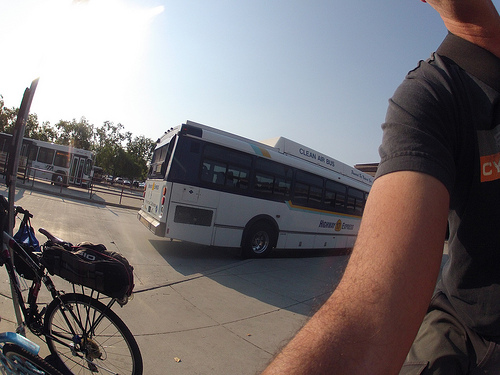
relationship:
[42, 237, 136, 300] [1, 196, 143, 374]
bag on bicycle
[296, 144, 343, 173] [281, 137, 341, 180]
writting on side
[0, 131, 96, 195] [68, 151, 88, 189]
bus has double doors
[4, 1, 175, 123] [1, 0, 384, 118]
sun glare in sky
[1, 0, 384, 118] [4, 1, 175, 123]
blue sky with white sun glare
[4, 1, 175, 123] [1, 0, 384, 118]
white glare in sky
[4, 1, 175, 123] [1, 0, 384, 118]
sunglare in sky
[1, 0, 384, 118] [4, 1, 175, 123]
sky has clouds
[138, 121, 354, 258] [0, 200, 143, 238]
bus on road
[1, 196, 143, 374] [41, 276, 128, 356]
bicycle has a bracket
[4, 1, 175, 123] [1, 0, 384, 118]
sunlight glare in sky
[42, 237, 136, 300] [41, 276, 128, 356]
bag on bracket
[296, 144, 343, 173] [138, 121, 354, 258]
sign on bus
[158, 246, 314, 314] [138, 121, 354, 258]
shadow of bus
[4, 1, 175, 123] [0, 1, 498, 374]
sunlight bright day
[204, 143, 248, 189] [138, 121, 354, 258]
windows on bus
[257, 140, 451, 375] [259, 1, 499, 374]
arm from a male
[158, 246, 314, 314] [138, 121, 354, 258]
shadow from bus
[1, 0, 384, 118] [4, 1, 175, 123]
sky has a sun glare